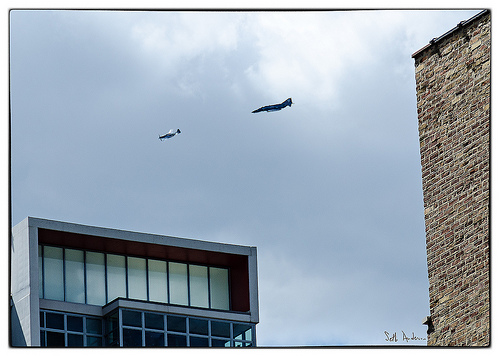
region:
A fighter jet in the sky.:
[244, 95, 302, 129]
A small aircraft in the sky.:
[156, 122, 188, 146]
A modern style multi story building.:
[9, 205, 274, 348]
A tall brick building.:
[410, 8, 497, 337]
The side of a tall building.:
[6, 210, 43, 347]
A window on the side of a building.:
[188, 257, 208, 309]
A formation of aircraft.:
[150, 93, 301, 143]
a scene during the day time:
[17, 12, 494, 353]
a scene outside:
[17, 9, 488, 354]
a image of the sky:
[12, 5, 492, 345]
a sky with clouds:
[15, 6, 429, 338]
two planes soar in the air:
[100, 76, 327, 170]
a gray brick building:
[383, 11, 495, 355]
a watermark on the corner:
[372, 313, 497, 347]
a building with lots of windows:
[0, 205, 305, 355]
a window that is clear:
[165, 309, 193, 336]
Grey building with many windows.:
[10, 214, 261, 348]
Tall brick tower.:
[410, 9, 490, 347]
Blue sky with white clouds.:
[8, 8, 432, 348]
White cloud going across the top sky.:
[122, 11, 449, 103]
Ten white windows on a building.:
[33, 242, 231, 312]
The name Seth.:
[383, 331, 398, 343]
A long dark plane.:
[250, 98, 293, 113]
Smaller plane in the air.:
[155, 128, 182, 139]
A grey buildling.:
[10, 213, 260, 352]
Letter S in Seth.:
[384, 332, 390, 342]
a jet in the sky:
[251, 94, 293, 112]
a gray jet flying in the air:
[156, 130, 183, 140]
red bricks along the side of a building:
[411, 9, 490, 344]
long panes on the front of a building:
[40, 240, 232, 308]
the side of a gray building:
[14, 214, 30, 344]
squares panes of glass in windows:
[37, 307, 256, 347]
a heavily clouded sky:
[11, 10, 488, 344]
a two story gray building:
[10, 215, 260, 346]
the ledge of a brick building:
[408, 11, 488, 55]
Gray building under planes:
[4, 217, 263, 354]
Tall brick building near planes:
[408, 11, 483, 346]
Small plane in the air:
[151, 126, 183, 141]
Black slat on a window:
[62, 245, 70, 303]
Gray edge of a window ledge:
[103, 295, 258, 321]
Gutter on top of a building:
[408, 9, 480, 56]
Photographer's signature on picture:
[383, 324, 480, 342]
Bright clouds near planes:
[133, 12, 431, 107]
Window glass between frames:
[46, 245, 63, 300]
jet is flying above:
[251, 95, 295, 115]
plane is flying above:
[160, 126, 180, 141]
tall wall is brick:
[414, 12, 490, 355]